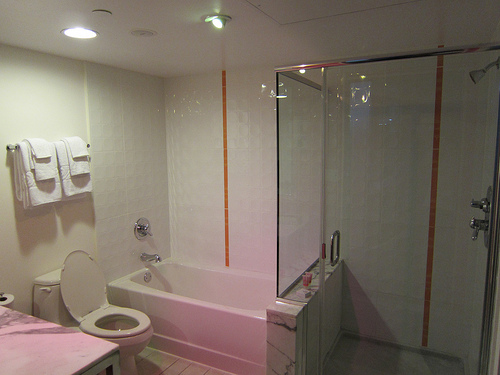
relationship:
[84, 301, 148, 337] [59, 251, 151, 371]
seat on toilet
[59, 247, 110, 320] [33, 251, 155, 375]
lid on toilet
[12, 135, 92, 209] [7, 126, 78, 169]
towels on rack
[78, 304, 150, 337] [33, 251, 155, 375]
seat on toilet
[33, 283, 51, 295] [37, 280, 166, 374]
handle on toilet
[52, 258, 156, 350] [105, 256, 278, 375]
toilet next to bathtub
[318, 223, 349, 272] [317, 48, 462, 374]
handle on a door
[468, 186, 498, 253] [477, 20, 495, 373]
valves on wall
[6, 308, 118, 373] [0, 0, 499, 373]
countertop in bathroom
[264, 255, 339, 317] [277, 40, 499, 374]
shelf in shower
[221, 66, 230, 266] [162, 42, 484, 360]
line adorning wall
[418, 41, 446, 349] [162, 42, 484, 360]
stripe adorning wall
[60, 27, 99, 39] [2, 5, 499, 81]
light on ceiling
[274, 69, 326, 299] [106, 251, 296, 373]
divider between bathtub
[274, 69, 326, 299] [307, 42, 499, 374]
divider between shower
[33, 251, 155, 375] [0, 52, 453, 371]
toilet in bathroom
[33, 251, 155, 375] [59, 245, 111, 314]
toilet with lid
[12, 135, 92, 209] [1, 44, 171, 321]
towels hanging on wall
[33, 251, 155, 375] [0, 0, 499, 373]
toilet in bathroom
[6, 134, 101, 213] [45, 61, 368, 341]
white towels in a bathroom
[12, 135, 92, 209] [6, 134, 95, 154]
towels on a bar